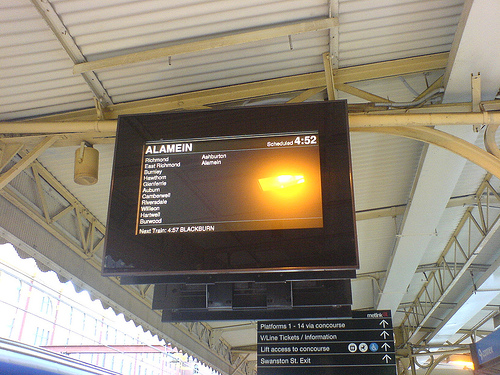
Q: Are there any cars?
A: No, there are no cars.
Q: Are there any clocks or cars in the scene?
A: No, there are no cars or clocks.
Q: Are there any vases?
A: No, there are no vases.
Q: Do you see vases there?
A: No, there are no vases.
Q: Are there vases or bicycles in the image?
A: No, there are no vases or bicycles.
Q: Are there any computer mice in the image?
A: No, there are no computer mice.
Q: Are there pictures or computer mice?
A: No, there are no computer mice or pictures.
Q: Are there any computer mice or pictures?
A: No, there are no computer mice or pictures.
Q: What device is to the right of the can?
A: The device is a screen.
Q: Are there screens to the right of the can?
A: Yes, there is a screen to the right of the can.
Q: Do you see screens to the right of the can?
A: Yes, there is a screen to the right of the can.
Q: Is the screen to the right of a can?
A: Yes, the screen is to the right of a can.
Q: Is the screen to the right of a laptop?
A: No, the screen is to the right of a can.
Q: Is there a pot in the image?
A: No, there are no pots.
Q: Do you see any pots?
A: No, there are no pots.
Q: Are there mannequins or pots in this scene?
A: No, there are no pots or mannequins.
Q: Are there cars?
A: No, there are no cars.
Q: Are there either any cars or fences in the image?
A: No, there are no cars or fences.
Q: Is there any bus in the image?
A: No, there are no buses.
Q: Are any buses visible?
A: No, there are no buses.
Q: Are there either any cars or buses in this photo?
A: No, there are no buses or cars.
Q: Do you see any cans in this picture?
A: Yes, there is a can.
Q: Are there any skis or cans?
A: Yes, there is a can.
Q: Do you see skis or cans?
A: Yes, there is a can.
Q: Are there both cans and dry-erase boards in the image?
A: No, there is a can but no dry-erase boards.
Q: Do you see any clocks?
A: No, there are no clocks.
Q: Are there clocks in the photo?
A: No, there are no clocks.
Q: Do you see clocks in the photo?
A: No, there are no clocks.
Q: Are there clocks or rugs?
A: No, there are no clocks or rugs.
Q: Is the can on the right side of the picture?
A: No, the can is on the left of the image.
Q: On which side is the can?
A: The can is on the left of the image.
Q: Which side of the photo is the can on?
A: The can is on the left of the image.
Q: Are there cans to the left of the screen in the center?
A: Yes, there is a can to the left of the screen.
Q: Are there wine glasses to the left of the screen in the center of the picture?
A: No, there is a can to the left of the screen.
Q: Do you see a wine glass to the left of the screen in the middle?
A: No, there is a can to the left of the screen.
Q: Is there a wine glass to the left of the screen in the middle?
A: No, there is a can to the left of the screen.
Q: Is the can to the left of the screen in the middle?
A: Yes, the can is to the left of the screen.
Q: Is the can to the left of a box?
A: No, the can is to the left of the screen.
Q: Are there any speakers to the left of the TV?
A: No, there is a can to the left of the TV.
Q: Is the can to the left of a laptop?
A: No, the can is to the left of the television.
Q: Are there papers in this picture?
A: No, there are no papers.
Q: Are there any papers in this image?
A: No, there are no papers.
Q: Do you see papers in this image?
A: No, there are no papers.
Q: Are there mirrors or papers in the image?
A: No, there are no papers or mirrors.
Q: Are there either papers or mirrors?
A: No, there are no papers or mirrors.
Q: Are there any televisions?
A: Yes, there is a television.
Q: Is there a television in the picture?
A: Yes, there is a television.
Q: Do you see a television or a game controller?
A: Yes, there is a television.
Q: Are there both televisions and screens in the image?
A: Yes, there are both a television and a screen.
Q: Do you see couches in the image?
A: No, there are no couches.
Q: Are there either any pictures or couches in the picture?
A: No, there are no couches or pictures.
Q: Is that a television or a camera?
A: That is a television.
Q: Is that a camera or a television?
A: That is a television.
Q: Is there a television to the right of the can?
A: Yes, there is a television to the right of the can.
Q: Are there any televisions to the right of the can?
A: Yes, there is a television to the right of the can.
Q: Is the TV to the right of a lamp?
A: No, the TV is to the right of the can.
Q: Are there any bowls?
A: No, there are no bowls.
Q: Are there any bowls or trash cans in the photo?
A: No, there are no bowls or trash cans.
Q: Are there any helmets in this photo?
A: No, there are no helmets.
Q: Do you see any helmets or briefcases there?
A: No, there are no helmets or briefcases.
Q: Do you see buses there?
A: No, there are no buses.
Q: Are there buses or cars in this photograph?
A: No, there are no buses or cars.